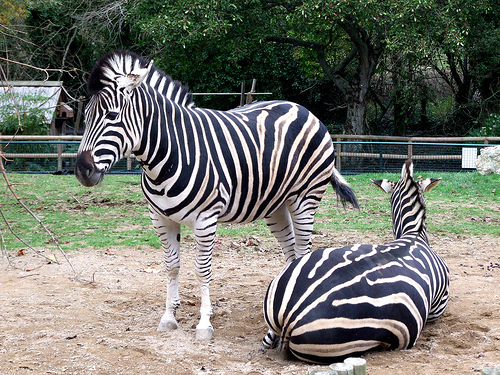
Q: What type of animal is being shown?
A: Zebras.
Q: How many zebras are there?
A: Two.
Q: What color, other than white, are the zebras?
A: Black.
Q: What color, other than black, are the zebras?
A: Whtie.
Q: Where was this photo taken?
A: Zoo.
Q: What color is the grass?
A: Green.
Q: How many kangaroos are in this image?
A: Zero.